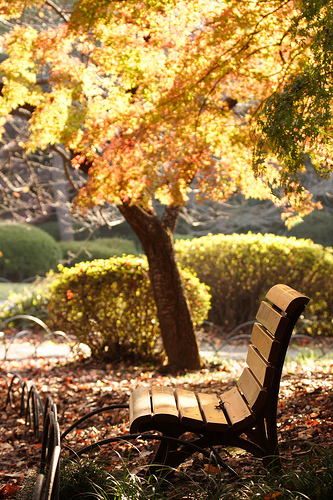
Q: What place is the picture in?
A: It is at the park.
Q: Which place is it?
A: It is a park.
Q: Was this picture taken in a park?
A: Yes, it was taken in a park.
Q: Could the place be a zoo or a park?
A: It is a park.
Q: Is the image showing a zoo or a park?
A: It is showing a park.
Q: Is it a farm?
A: No, it is a park.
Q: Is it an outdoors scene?
A: Yes, it is outdoors.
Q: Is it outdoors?
A: Yes, it is outdoors.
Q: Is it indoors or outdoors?
A: It is outdoors.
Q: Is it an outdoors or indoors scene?
A: It is outdoors.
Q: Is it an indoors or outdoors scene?
A: It is outdoors.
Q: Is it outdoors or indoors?
A: It is outdoors.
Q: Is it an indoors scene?
A: No, it is outdoors.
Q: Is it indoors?
A: No, it is outdoors.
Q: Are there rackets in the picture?
A: No, there are no rackets.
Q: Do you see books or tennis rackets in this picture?
A: No, there are no tennis rackets or books.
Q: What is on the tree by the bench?
A: The leaves are on the tree.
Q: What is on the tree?
A: The leaves are on the tree.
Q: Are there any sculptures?
A: No, there are no sculptures.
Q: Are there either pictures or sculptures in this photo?
A: No, there are no sculptures or pictures.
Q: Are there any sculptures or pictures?
A: No, there are no sculptures or pictures.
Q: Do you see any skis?
A: No, there are no skis.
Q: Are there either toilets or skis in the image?
A: No, there are no skis or toilets.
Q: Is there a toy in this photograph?
A: No, there are no toys.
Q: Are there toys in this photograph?
A: No, there are no toys.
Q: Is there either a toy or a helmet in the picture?
A: No, there are no toys or helmets.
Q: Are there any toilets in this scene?
A: No, there are no toilets.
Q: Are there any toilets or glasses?
A: No, there are no toilets or glasses.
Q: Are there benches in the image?
A: Yes, there is a bench.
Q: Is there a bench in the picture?
A: Yes, there is a bench.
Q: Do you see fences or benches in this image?
A: Yes, there is a bench.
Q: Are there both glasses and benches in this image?
A: No, there is a bench but no glasses.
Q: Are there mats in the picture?
A: No, there are no mats.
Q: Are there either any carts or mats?
A: No, there are no mats or carts.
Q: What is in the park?
A: The bench is in the park.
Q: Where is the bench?
A: The bench is in the park.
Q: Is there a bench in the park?
A: Yes, there is a bench in the park.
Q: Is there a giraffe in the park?
A: No, there is a bench in the park.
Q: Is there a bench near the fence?
A: Yes, there is a bench near the fence.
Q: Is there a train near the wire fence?
A: No, there is a bench near the fence.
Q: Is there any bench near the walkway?
A: Yes, there is a bench near the walkway.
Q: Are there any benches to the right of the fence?
A: Yes, there is a bench to the right of the fence.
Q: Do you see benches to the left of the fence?
A: No, the bench is to the right of the fence.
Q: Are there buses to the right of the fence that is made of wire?
A: No, there is a bench to the right of the fence.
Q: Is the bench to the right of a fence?
A: Yes, the bench is to the right of a fence.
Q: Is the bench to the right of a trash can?
A: No, the bench is to the right of a fence.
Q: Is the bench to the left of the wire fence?
A: No, the bench is to the right of the fence.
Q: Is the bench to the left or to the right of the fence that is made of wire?
A: The bench is to the right of the fence.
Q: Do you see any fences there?
A: Yes, there is a fence.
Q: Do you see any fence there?
A: Yes, there is a fence.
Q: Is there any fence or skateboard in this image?
A: Yes, there is a fence.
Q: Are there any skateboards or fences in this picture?
A: Yes, there is a fence.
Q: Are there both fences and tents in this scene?
A: No, there is a fence but no tents.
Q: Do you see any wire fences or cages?
A: Yes, there is a wire fence.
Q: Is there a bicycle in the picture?
A: No, there are no bicycles.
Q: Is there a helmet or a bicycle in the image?
A: No, there are no bicycles or helmets.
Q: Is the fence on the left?
A: Yes, the fence is on the left of the image.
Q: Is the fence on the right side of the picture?
A: No, the fence is on the left of the image.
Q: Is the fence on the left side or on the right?
A: The fence is on the left of the image.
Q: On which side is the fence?
A: The fence is on the left of the image.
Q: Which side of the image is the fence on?
A: The fence is on the left of the image.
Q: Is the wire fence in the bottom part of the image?
A: Yes, the fence is in the bottom of the image.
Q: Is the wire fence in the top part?
A: No, the fence is in the bottom of the image.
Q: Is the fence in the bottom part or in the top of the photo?
A: The fence is in the bottom of the image.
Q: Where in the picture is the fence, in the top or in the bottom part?
A: The fence is in the bottom of the image.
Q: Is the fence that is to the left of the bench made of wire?
A: Yes, the fence is made of wire.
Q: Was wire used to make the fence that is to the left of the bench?
A: Yes, the fence is made of wire.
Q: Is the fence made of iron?
A: No, the fence is made of wire.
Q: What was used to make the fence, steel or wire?
A: The fence is made of wire.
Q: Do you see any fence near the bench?
A: Yes, there is a fence near the bench.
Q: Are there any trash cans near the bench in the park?
A: No, there is a fence near the bench.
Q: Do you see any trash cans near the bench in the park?
A: No, there is a fence near the bench.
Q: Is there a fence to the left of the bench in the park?
A: Yes, there is a fence to the left of the bench.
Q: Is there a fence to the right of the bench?
A: No, the fence is to the left of the bench.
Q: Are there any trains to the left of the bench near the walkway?
A: No, there is a fence to the left of the bench.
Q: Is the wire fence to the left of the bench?
A: Yes, the fence is to the left of the bench.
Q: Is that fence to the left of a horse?
A: No, the fence is to the left of the bench.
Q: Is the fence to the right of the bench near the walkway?
A: No, the fence is to the left of the bench.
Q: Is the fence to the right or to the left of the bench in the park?
A: The fence is to the left of the bench.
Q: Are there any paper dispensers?
A: No, there are no paper dispensers.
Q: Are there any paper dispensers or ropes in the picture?
A: No, there are no paper dispensers or ropes.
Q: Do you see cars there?
A: No, there are no cars.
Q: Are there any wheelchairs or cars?
A: No, there are no cars or wheelchairs.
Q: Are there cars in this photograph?
A: No, there are no cars.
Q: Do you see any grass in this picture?
A: Yes, there is grass.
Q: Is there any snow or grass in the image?
A: Yes, there is grass.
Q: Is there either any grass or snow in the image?
A: Yes, there is grass.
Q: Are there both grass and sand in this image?
A: No, there is grass but no sand.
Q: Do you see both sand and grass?
A: No, there is grass but no sand.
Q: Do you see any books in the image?
A: No, there are no books.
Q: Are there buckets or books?
A: No, there are no books or buckets.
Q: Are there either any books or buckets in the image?
A: No, there are no books or buckets.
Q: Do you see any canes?
A: No, there are no canes.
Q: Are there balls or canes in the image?
A: No, there are no canes or balls.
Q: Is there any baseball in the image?
A: No, there are no baseballs.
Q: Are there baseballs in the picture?
A: No, there are no baseballs.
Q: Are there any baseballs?
A: No, there are no baseballs.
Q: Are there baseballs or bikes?
A: No, there are no baseballs or bikes.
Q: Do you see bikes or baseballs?
A: No, there are no baseballs or bikes.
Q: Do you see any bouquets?
A: No, there are no bouquets.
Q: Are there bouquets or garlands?
A: No, there are no bouquets or garlands.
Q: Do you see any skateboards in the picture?
A: No, there are no skateboards.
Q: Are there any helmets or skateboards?
A: No, there are no skateboards or helmets.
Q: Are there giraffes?
A: No, there are no giraffes.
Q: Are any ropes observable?
A: No, there are no ropes.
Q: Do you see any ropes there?
A: No, there are no ropes.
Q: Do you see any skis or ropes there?
A: No, there are no ropes or skis.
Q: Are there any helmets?
A: No, there are no helmets.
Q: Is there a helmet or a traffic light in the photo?
A: No, there are no helmets or traffic lights.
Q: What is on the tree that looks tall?
A: The leaves are on the tree.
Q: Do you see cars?
A: No, there are no cars.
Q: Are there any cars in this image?
A: No, there are no cars.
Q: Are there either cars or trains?
A: No, there are no cars or trains.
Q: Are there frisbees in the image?
A: No, there are no frisbees.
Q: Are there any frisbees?
A: No, there are no frisbees.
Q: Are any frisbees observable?
A: No, there are no frisbees.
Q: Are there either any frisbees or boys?
A: No, there are no frisbees or boys.